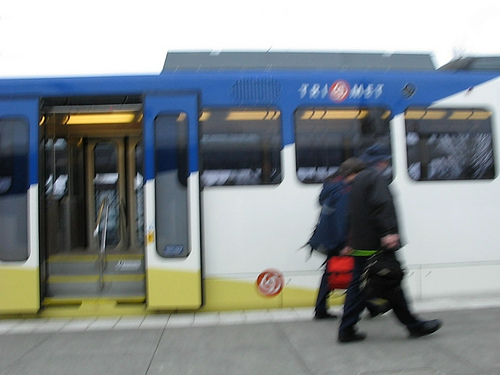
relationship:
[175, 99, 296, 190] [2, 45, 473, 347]
window on train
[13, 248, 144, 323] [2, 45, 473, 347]
step on train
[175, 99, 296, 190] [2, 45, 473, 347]
window of train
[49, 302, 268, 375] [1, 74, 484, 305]
sidewalk near a train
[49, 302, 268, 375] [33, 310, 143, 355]
sidewalk near entryway